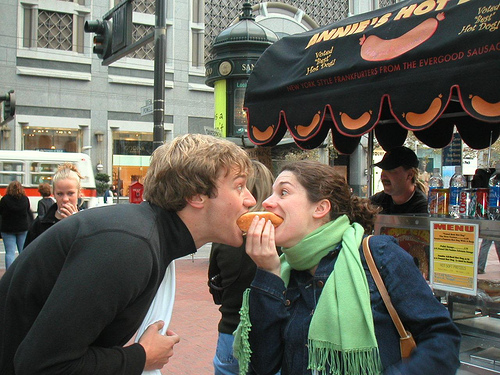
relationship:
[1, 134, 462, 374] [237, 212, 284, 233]
people are sharing food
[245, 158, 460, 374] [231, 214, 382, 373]
girl wearing a scarf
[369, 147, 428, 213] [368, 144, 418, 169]
man wearing a hat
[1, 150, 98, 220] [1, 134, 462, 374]
vehicle behind people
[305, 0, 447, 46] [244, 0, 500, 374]
annie's hot on stand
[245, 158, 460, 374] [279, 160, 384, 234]
girl has hair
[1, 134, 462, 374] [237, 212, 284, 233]
people are enjoying food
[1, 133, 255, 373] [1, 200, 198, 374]
man wearing a turtleneck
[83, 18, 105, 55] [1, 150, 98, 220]
traffic light above vehicle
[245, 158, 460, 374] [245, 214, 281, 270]
girl has a hand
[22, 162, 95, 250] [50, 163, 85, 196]
female has blonde hair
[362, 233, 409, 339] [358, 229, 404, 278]
strap on shoulder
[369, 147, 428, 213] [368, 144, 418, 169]
man wearing hat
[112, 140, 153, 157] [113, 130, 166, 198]
sign in store window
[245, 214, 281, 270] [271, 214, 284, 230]
hand near mouth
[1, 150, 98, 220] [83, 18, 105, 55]
vehicle under traffic light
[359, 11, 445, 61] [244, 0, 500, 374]
hot dog graphic on stand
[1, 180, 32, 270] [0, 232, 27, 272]
woman wearing jeans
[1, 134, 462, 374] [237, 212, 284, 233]
people eating food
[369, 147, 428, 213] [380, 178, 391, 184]
man has a mustache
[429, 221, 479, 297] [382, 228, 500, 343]
menu attached to window